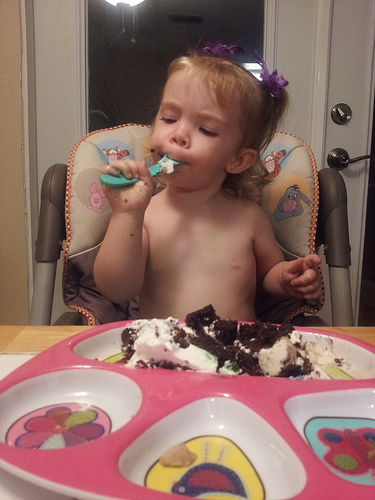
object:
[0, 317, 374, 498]
pink/white plate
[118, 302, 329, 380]
cake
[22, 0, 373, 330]
door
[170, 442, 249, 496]
bird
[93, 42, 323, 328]
child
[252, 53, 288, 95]
bow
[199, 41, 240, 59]
bow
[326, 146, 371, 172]
handle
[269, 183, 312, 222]
animal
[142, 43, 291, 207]
blonde hair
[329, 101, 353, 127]
lock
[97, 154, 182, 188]
spoon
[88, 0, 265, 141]
window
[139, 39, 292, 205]
hair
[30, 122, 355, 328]
chair